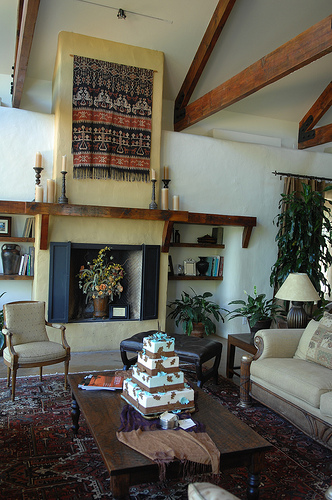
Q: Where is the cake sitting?
A: Coffee table.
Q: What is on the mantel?
A: Candles.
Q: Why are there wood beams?
A: Support.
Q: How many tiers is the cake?
A: Four.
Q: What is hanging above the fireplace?
A: Rug.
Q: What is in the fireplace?
A: Flowers.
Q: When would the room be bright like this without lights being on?
A: Daytime.